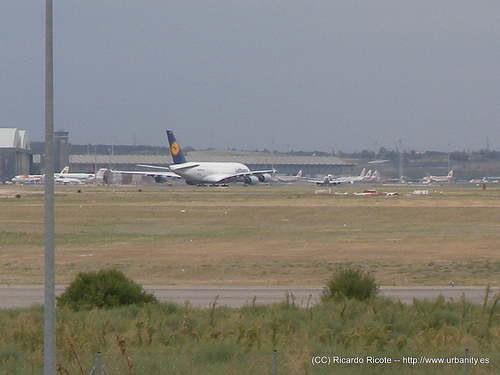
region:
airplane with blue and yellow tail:
[95, 126, 276, 190]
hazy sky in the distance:
[277, 57, 440, 130]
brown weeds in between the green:
[90, 315, 168, 371]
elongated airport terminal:
[72, 147, 361, 176]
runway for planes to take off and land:
[36, 285, 481, 310]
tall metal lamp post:
[38, 34, 65, 367]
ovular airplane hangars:
[1, 125, 33, 179]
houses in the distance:
[402, 140, 459, 162]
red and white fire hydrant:
[479, 178, 487, 189]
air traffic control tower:
[52, 120, 72, 172]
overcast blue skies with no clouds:
[120, 21, 477, 100]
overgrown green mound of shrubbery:
[59, 264, 159, 324]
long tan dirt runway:
[85, 193, 499, 218]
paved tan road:
[159, 281, 305, 303]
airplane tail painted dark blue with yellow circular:
[155, 123, 188, 163]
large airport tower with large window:
[53, 125, 74, 173]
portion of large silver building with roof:
[248, 148, 359, 173]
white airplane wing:
[223, 168, 295, 179]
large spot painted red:
[359, 183, 382, 205]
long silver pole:
[88, 139, 100, 181]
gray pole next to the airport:
[41, 1, 56, 371]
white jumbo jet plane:
[133, 130, 274, 185]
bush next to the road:
[61, 268, 148, 308]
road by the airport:
[5, 278, 493, 304]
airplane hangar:
[7, 120, 37, 177]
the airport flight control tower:
[51, 121, 71, 176]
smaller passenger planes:
[13, 170, 114, 187]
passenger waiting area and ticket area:
[67, 150, 354, 175]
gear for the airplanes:
[316, 185, 431, 201]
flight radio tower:
[394, 134, 409, 189]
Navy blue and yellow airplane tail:
[156, 123, 193, 168]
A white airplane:
[151, 151, 266, 192]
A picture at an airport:
[0, 6, 493, 373]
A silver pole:
[35, 7, 69, 373]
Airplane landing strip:
[0, 265, 496, 335]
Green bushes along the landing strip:
[56, 271, 392, 309]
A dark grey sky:
[77, 8, 482, 140]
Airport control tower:
[49, 127, 77, 185]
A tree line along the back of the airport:
[63, 140, 499, 170]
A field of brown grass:
[65, 187, 478, 269]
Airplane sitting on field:
[140, 122, 277, 193]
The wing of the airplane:
[164, 124, 180, 166]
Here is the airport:
[3, 124, 494, 202]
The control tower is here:
[52, 127, 73, 175]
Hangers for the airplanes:
[1, 122, 33, 181]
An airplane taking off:
[420, 167, 457, 183]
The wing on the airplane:
[219, 163, 278, 186]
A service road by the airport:
[2, 280, 498, 310]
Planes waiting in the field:
[292, 165, 458, 182]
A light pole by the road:
[41, 0, 61, 374]